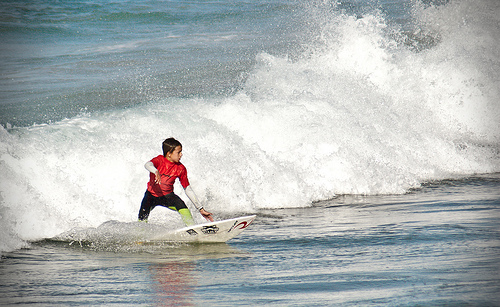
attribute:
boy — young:
[135, 135, 219, 237]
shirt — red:
[145, 152, 191, 201]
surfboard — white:
[158, 207, 256, 246]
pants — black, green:
[134, 189, 199, 230]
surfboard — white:
[144, 210, 257, 248]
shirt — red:
[145, 151, 189, 197]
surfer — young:
[135, 137, 217, 229]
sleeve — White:
[181, 185, 202, 214]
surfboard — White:
[148, 212, 258, 242]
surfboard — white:
[137, 136, 214, 225]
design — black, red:
[185, 218, 247, 234]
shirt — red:
[144, 156, 190, 196]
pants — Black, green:
[137, 189, 193, 227]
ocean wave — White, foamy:
[0, 2, 498, 254]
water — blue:
[0, 0, 496, 305]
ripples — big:
[288, 220, 469, 243]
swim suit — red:
[143, 153, 189, 198]